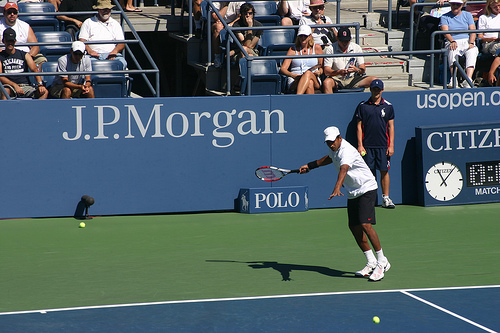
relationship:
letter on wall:
[190, 110, 212, 138] [0, 95, 253, 219]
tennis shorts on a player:
[345, 190, 377, 230] [297, 125, 392, 283]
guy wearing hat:
[353, 77, 399, 210] [370, 79, 385, 88]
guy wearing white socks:
[298, 124, 395, 283] [360, 247, 385, 263]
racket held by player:
[250, 161, 304, 191] [296, 119, 396, 290]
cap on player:
[318, 121, 348, 147] [296, 119, 396, 290]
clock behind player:
[422, 159, 465, 206] [296, 119, 396, 290]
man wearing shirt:
[77, 4, 125, 58] [74, 20, 128, 59]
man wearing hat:
[77, 4, 125, 58] [81, 1, 121, 19]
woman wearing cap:
[283, 22, 322, 85] [291, 20, 311, 40]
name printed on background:
[52, 96, 282, 145] [13, 99, 343, 208]